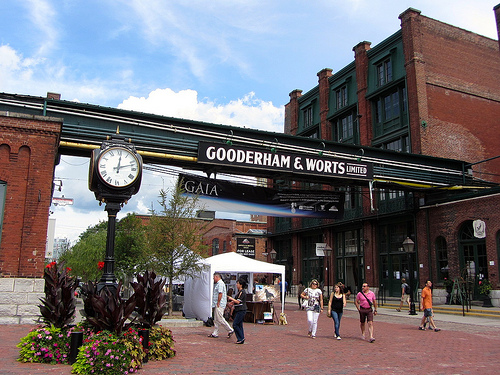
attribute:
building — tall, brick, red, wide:
[310, 30, 498, 242]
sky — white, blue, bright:
[0, 1, 495, 258]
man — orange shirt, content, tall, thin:
[417, 279, 441, 331]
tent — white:
[175, 241, 298, 333]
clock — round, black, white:
[98, 147, 138, 187]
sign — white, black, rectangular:
[197, 134, 366, 175]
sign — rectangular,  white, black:
[197, 140, 377, 189]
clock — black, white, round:
[65, 157, 150, 247]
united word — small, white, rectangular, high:
[345, 160, 369, 181]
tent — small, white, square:
[187, 245, 314, 333]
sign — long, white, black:
[142, 113, 410, 187]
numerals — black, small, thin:
[121, 149, 136, 168]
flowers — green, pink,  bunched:
[17, 255, 77, 367]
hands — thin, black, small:
[116, 155, 128, 173]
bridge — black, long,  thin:
[0, 90, 477, 191]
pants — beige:
[204, 299, 244, 334]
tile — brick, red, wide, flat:
[1, 297, 499, 372]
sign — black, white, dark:
[172, 173, 275, 203]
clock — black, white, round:
[97, 143, 142, 185]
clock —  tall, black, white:
[86, 119, 158, 224]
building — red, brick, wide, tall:
[285, 14, 498, 303]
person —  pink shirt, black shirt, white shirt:
[301, 273, 324, 312]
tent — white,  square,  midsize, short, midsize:
[184, 252, 290, 324]